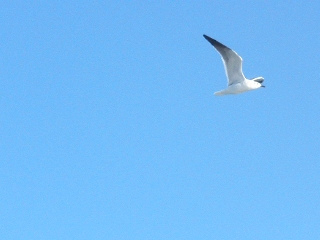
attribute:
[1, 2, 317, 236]
sky — blue, sunny, light blue, bright, black, cloudless, clear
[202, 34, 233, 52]
tip — black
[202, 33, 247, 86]
wing — extended, spread, grey, white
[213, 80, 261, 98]
body — white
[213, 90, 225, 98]
tail — gray, white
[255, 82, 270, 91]
head — white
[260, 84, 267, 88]
beak — black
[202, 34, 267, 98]
bird — white, flying, gray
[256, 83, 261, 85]
eye — small